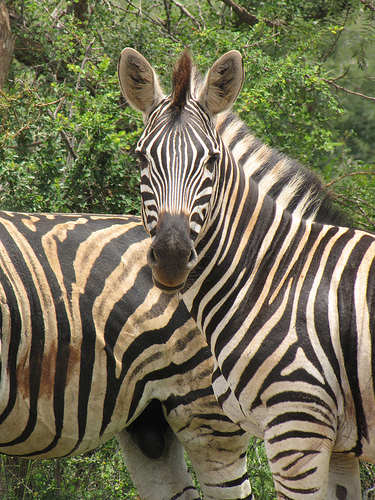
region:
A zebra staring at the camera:
[118, 44, 373, 498]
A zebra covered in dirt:
[0, 205, 261, 499]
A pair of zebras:
[0, 41, 374, 497]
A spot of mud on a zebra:
[12, 338, 83, 402]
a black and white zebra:
[119, 40, 373, 498]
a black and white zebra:
[0, 202, 257, 499]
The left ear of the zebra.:
[116, 44, 163, 115]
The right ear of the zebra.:
[202, 51, 239, 111]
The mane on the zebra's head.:
[169, 48, 191, 115]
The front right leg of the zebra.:
[266, 402, 330, 499]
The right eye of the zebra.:
[203, 149, 223, 166]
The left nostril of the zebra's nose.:
[148, 242, 156, 264]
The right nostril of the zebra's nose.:
[184, 248, 196, 266]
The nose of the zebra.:
[146, 236, 199, 274]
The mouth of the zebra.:
[151, 276, 184, 292]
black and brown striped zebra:
[116, 48, 374, 429]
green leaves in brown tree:
[44, 103, 78, 129]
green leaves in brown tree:
[11, 54, 41, 84]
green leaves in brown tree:
[282, 44, 308, 69]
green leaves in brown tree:
[300, 114, 339, 142]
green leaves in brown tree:
[310, 13, 340, 48]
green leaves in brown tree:
[28, 63, 60, 103]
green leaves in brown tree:
[46, 103, 71, 131]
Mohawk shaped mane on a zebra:
[174, 47, 189, 116]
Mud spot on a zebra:
[8, 337, 83, 403]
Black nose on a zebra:
[146, 226, 199, 270]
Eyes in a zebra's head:
[131, 145, 223, 170]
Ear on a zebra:
[203, 48, 243, 113]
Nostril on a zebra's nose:
[148, 248, 161, 266]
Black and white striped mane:
[215, 109, 340, 223]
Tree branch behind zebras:
[228, 3, 297, 34]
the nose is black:
[136, 204, 199, 290]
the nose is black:
[142, 220, 192, 289]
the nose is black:
[148, 213, 195, 279]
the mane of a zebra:
[164, 39, 202, 118]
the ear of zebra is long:
[110, 42, 249, 120]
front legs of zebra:
[251, 415, 363, 499]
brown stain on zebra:
[15, 336, 84, 408]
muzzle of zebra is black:
[140, 204, 203, 297]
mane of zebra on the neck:
[222, 110, 358, 238]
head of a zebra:
[106, 40, 243, 303]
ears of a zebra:
[113, 41, 246, 129]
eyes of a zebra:
[135, 146, 219, 178]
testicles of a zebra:
[126, 406, 172, 462]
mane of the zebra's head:
[170, 48, 195, 126]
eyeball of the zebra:
[202, 151, 219, 172]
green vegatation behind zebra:
[1, 6, 371, 235]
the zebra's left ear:
[199, 43, 244, 119]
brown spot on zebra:
[14, 341, 88, 398]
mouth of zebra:
[149, 271, 185, 293]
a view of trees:
[74, 453, 139, 492]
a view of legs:
[200, 444, 247, 491]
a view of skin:
[238, 276, 281, 344]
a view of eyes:
[180, 128, 229, 195]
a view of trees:
[88, 466, 118, 494]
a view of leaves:
[77, 475, 116, 499]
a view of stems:
[61, 133, 100, 191]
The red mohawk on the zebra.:
[167, 47, 194, 110]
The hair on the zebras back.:
[214, 100, 351, 226]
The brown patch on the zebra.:
[4, 340, 84, 398]